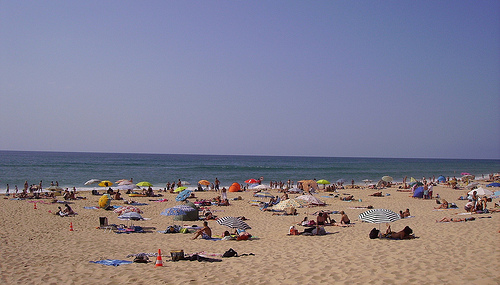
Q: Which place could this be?
A: It is a beach.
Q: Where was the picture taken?
A: It was taken at the beach.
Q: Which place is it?
A: It is a beach.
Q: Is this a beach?
A: Yes, it is a beach.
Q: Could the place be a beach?
A: Yes, it is a beach.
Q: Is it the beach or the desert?
A: It is the beach.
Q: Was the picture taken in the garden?
A: No, the picture was taken in the beach.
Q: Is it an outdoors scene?
A: Yes, it is outdoors.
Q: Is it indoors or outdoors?
A: It is outdoors.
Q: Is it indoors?
A: No, it is outdoors.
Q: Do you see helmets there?
A: No, there are no helmets.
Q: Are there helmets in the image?
A: No, there are no helmets.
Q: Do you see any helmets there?
A: No, there are no helmets.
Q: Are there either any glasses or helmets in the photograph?
A: No, there are no helmets or glasses.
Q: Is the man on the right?
A: Yes, the man is on the right of the image.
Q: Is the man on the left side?
A: No, the man is on the right of the image.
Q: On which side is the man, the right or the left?
A: The man is on the right of the image.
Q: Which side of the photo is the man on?
A: The man is on the right of the image.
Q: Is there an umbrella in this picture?
A: Yes, there is an umbrella.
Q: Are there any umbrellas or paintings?
A: Yes, there is an umbrella.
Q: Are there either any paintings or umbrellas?
A: Yes, there is an umbrella.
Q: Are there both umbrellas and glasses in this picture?
A: No, there is an umbrella but no glasses.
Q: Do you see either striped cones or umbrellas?
A: Yes, there is a striped umbrella.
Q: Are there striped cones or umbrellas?
A: Yes, there is a striped umbrella.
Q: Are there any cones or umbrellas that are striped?
A: Yes, the umbrella is striped.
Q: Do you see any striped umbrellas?
A: Yes, there is a striped umbrella.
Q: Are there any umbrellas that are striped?
A: Yes, there is an umbrella that is striped.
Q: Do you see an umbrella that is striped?
A: Yes, there is an umbrella that is striped.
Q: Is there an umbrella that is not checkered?
A: Yes, there is a striped umbrella.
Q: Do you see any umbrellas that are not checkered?
A: Yes, there is a striped umbrella.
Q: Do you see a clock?
A: No, there are no clocks.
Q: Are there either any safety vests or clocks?
A: No, there are no clocks or safety vests.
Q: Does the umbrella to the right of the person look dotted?
A: No, the umbrella is striped.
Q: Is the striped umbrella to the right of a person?
A: Yes, the umbrella is to the right of a person.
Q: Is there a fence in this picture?
A: No, there are no fences.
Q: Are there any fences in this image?
A: No, there are no fences.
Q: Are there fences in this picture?
A: No, there are no fences.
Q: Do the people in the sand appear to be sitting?
A: Yes, the people are sitting.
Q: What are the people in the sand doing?
A: The people are sitting.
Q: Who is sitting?
A: The people are sitting.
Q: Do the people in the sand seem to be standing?
A: No, the people are sitting.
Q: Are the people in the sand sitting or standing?
A: The people are sitting.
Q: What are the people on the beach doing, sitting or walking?
A: The people are sitting.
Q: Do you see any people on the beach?
A: Yes, there are people on the beach.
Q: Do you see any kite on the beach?
A: No, there are people on the beach.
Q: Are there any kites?
A: No, there are no kites.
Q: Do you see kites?
A: No, there are no kites.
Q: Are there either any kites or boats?
A: No, there are no kites or boats.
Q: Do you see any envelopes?
A: No, there are no envelopes.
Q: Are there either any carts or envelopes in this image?
A: No, there are no envelopes or carts.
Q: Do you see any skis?
A: No, there are no skis.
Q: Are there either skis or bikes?
A: No, there are no skis or bikes.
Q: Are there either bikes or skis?
A: No, there are no skis or bikes.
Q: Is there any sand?
A: Yes, there is sand.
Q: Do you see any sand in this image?
A: Yes, there is sand.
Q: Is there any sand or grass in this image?
A: Yes, there is sand.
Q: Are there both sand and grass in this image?
A: No, there is sand but no grass.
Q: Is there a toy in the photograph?
A: No, there are no toys.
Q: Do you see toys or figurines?
A: No, there are no toys or figurines.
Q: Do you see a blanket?
A: Yes, there is a blanket.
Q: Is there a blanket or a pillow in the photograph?
A: Yes, there is a blanket.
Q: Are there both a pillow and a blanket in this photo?
A: No, there is a blanket but no pillows.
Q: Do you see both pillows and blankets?
A: No, there is a blanket but no pillows.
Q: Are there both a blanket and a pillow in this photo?
A: No, there is a blanket but no pillows.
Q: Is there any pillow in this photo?
A: No, there are no pillows.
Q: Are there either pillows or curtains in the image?
A: No, there are no pillows or curtains.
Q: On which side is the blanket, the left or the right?
A: The blanket is on the left of the image.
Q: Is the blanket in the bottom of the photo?
A: Yes, the blanket is in the bottom of the image.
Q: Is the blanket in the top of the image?
A: No, the blanket is in the bottom of the image.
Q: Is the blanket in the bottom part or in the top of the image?
A: The blanket is in the bottom of the image.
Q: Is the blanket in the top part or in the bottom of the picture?
A: The blanket is in the bottom of the image.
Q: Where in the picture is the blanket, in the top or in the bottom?
A: The blanket is in the bottom of the image.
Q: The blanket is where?
A: The blanket is in the sand.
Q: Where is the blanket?
A: The blanket is in the sand.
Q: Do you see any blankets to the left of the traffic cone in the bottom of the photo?
A: Yes, there is a blanket to the left of the traffic cone.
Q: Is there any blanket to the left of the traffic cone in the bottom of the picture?
A: Yes, there is a blanket to the left of the traffic cone.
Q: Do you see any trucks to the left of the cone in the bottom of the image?
A: No, there is a blanket to the left of the cone.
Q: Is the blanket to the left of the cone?
A: Yes, the blanket is to the left of the cone.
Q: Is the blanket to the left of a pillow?
A: No, the blanket is to the left of the cone.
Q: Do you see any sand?
A: Yes, there is sand.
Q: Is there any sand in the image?
A: Yes, there is sand.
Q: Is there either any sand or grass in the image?
A: Yes, there is sand.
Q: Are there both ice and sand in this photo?
A: No, there is sand but no ice.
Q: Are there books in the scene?
A: No, there are no books.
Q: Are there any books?
A: No, there are no books.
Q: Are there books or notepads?
A: No, there are no books or notepads.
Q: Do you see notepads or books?
A: No, there are no books or notepads.